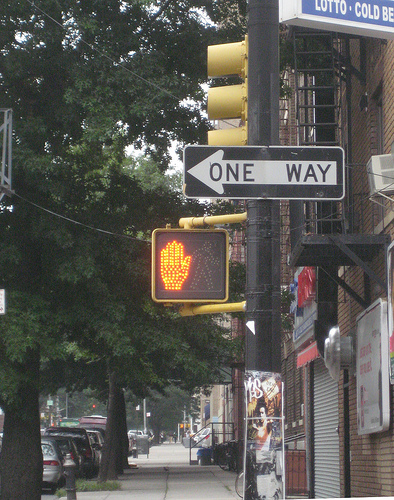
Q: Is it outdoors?
A: Yes, it is outdoors.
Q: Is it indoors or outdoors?
A: It is outdoors.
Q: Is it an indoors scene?
A: No, it is outdoors.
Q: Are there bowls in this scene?
A: No, there are no bowls.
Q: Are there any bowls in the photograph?
A: No, there are no bowls.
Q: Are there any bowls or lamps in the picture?
A: No, there are no bowls or lamps.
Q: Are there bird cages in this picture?
A: No, there are no bird cages.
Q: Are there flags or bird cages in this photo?
A: No, there are no bird cages or flags.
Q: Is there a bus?
A: No, there are no buses.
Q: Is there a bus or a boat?
A: No, there are no buses or boats.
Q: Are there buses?
A: No, there are no buses.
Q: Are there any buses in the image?
A: No, there are no buses.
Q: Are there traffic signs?
A: Yes, there is a traffic sign.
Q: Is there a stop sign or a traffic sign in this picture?
A: Yes, there is a traffic sign.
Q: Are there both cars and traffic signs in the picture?
A: Yes, there are both a traffic sign and a car.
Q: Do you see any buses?
A: No, there are no buses.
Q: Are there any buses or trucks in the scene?
A: No, there are no buses or trucks.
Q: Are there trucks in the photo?
A: No, there are no trucks.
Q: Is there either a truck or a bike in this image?
A: No, there are no trucks or bikes.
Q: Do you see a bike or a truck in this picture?
A: No, there are no trucks or bikes.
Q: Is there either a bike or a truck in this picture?
A: No, there are no trucks or bikes.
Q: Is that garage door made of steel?
A: Yes, the garage door is made of steel.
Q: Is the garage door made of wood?
A: No, the garage door is made of steel.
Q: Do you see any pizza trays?
A: No, there are no pizza trays.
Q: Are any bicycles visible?
A: No, there are no bicycles.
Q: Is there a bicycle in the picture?
A: No, there are no bicycles.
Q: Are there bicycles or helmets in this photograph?
A: No, there are no bicycles or helmets.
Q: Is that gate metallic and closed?
A: Yes, the gate is metallic and closed.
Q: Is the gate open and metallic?
A: No, the gate is metallic but closed.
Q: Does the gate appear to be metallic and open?
A: No, the gate is metallic but closed.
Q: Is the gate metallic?
A: Yes, the gate is metallic.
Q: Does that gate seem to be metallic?
A: Yes, the gate is metallic.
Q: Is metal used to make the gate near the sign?
A: Yes, the gate is made of metal.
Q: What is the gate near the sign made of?
A: The gate is made of metal.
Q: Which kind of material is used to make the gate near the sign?
A: The gate is made of metal.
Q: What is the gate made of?
A: The gate is made of metal.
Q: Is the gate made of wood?
A: No, the gate is made of metal.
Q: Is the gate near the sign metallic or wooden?
A: The gate is metallic.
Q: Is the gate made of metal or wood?
A: The gate is made of metal.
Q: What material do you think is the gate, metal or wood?
A: The gate is made of metal.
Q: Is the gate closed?
A: Yes, the gate is closed.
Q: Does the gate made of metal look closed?
A: Yes, the gate is closed.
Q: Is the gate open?
A: No, the gate is closed.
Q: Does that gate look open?
A: No, the gate is closed.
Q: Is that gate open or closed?
A: The gate is closed.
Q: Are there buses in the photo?
A: No, there are no buses.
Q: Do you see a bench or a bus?
A: No, there are no buses or benches.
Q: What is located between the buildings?
A: The street is between the buildings.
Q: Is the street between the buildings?
A: Yes, the street is between the buildings.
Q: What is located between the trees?
A: The street is between the trees.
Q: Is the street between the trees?
A: Yes, the street is between the trees.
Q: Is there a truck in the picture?
A: No, there are no trucks.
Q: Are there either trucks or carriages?
A: No, there are no trucks or carriages.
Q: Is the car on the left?
A: Yes, the car is on the left of the image.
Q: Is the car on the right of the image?
A: No, the car is on the left of the image.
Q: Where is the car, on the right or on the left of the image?
A: The car is on the left of the image.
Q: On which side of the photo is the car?
A: The car is on the left of the image.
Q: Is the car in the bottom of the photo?
A: Yes, the car is in the bottom of the image.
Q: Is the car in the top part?
A: No, the car is in the bottom of the image.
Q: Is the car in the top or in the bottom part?
A: The car is in the bottom of the image.